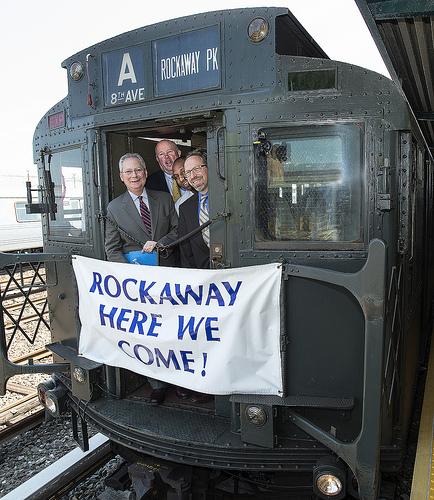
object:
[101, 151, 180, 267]
person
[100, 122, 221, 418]
doorway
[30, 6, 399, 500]
back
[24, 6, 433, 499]
train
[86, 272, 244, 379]
words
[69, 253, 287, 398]
banner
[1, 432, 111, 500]
track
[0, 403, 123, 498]
gravel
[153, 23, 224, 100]
sign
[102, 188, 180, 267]
suit and tie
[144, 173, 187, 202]
suit and tie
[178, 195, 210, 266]
suit and tie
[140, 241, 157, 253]
hand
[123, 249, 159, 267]
folder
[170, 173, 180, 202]
yellow tie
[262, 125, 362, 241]
window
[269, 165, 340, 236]
reflection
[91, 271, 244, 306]
destination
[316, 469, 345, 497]
headlight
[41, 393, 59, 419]
headlight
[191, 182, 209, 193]
beard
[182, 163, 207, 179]
glasses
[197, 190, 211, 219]
light blue shirt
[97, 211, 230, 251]
safety strap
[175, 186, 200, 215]
suit and tie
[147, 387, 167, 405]
shoe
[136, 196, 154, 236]
tie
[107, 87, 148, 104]
words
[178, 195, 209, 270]
black jacket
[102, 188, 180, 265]
light grey jacket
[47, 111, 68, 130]
exp sign